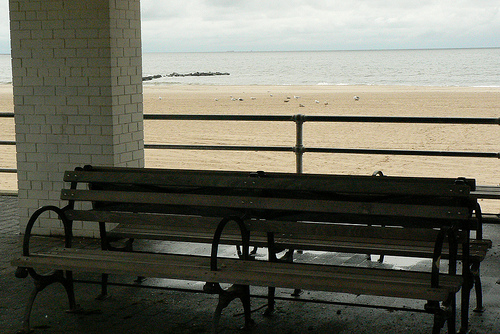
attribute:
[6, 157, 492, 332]
beach — empty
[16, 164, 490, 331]
bench — wooden, long, two-part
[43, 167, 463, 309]
bench — wooden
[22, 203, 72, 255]
metal bars — black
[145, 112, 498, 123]
railing — metal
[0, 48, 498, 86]
ocean — background, distance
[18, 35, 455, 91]
water — ocean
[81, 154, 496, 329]
bench — black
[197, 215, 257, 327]
bar — black, round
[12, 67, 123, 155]
support —  building, bricks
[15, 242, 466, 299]
planks — wooden, bottom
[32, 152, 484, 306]
wooden bench — long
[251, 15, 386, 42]
sky — cloudy, overcast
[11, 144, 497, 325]
bench — wooden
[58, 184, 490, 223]
slate — wooden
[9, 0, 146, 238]
brick wall — white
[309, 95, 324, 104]
bird — white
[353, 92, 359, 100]
seagull — white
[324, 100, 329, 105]
seagull — white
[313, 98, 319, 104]
seagull — white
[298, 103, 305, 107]
seagull — white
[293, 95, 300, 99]
seagull — white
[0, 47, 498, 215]
beach — sandy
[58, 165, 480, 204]
slat — wooden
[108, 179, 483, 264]
slate — wooden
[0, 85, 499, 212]
beach — sandy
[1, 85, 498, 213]
sand — full 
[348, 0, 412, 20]
sky — blue, pale, cloudy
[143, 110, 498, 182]
railings — black, metal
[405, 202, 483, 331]
arm — rounded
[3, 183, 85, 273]
arm — rounded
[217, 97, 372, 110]
seagulls — white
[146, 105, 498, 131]
bars — metal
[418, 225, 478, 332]
bar — round